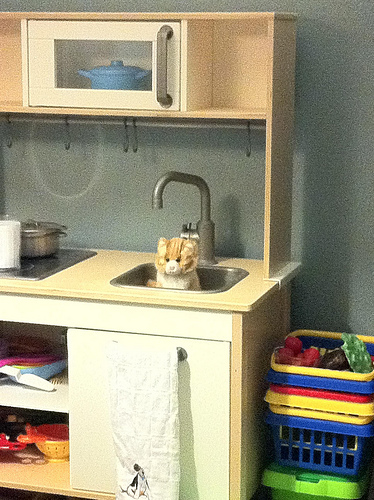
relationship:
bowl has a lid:
[73, 72, 157, 90] [83, 56, 148, 73]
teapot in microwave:
[83, 55, 161, 93] [20, 20, 188, 119]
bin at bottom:
[257, 464, 367, 498] [0, 452, 373, 497]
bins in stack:
[264, 387, 373, 430] [256, 317, 370, 498]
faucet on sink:
[151, 161, 224, 262] [108, 258, 249, 296]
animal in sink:
[143, 228, 212, 287] [113, 260, 258, 304]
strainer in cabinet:
[20, 424, 73, 465] [0, 407, 81, 487]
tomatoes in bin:
[280, 333, 320, 371] [263, 324, 373, 379]